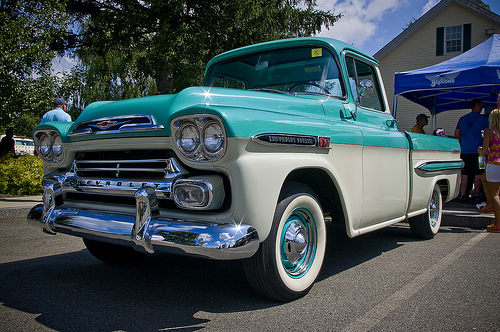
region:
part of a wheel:
[281, 213, 313, 283]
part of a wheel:
[275, 196, 324, 305]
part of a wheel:
[256, 180, 332, 285]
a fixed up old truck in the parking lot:
[28, 30, 468, 298]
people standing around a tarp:
[416, 103, 499, 224]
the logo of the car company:
[83, 116, 118, 129]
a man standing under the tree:
[1, 122, 16, 152]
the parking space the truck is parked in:
[8, 202, 463, 328]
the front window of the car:
[195, 43, 341, 94]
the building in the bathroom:
[367, 5, 494, 128]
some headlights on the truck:
[170, 117, 220, 157]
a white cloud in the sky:
[307, 1, 382, 44]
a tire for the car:
[268, 191, 330, 304]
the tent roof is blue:
[386, 35, 498, 120]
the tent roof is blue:
[380, 17, 487, 89]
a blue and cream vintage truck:
[43, 60, 436, 317]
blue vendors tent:
[390, 31, 499, 115]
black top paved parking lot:
[0, 215, 499, 330]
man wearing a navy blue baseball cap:
[38, 96, 75, 122]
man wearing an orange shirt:
[408, 111, 431, 136]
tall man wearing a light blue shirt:
[450, 95, 492, 210]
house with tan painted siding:
[368, 0, 499, 141]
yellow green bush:
[0, 150, 45, 195]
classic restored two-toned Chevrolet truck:
[24, 35, 466, 300]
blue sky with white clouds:
[11, 0, 498, 82]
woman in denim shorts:
[475, 106, 499, 236]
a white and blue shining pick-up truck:
[36, 33, 463, 303]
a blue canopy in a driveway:
[390, 32, 499, 108]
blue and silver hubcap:
[278, 203, 316, 275]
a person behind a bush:
[1, 124, 17, 158]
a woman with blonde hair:
[488, 106, 498, 138]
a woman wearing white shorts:
[483, 161, 498, 181]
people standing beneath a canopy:
[411, 96, 498, 203]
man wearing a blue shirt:
[455, 108, 490, 153]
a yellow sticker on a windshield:
[309, 46, 324, 58]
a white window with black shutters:
[436, 25, 473, 58]